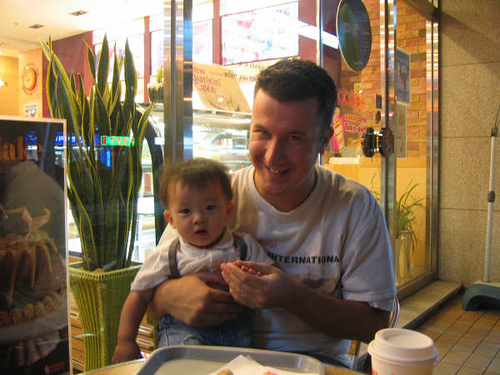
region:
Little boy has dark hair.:
[162, 163, 296, 255]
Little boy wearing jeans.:
[146, 305, 296, 368]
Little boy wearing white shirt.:
[143, 239, 252, 328]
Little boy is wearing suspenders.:
[158, 237, 218, 311]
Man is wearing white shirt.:
[274, 224, 461, 369]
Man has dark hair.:
[266, 90, 334, 118]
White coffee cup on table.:
[356, 327, 443, 371]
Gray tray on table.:
[156, 339, 228, 371]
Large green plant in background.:
[29, 89, 146, 368]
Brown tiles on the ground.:
[448, 327, 468, 365]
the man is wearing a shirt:
[148, 159, 408, 372]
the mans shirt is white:
[142, 154, 403, 368]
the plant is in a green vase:
[65, 256, 146, 373]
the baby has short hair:
[155, 152, 237, 217]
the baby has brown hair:
[153, 153, 238, 217]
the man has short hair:
[245, 56, 345, 151]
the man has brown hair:
[241, 46, 342, 159]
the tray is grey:
[130, 341, 328, 373]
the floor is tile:
[350, 274, 499, 374]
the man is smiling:
[261, 159, 291, 180]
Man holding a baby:
[111, 57, 391, 374]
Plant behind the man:
[31, 31, 150, 373]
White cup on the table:
[364, 325, 444, 373]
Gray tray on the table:
[136, 332, 331, 373]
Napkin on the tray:
[199, 347, 284, 373]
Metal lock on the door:
[357, 120, 401, 157]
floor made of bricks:
[416, 287, 498, 372]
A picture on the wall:
[0, 109, 77, 373]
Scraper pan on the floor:
[456, 119, 499, 315]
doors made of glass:
[323, 0, 443, 305]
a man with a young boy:
[108, 51, 423, 365]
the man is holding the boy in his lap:
[117, 35, 415, 360]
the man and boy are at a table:
[111, 57, 438, 373]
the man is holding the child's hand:
[110, 51, 430, 358]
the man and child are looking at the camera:
[114, 40, 417, 367]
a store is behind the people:
[68, 8, 478, 306]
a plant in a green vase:
[35, 36, 159, 356]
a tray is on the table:
[130, 317, 375, 373]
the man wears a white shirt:
[217, 63, 428, 344]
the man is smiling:
[201, 43, 433, 361]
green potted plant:
[61, 44, 136, 267]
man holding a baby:
[155, 69, 377, 339]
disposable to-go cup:
[369, 326, 438, 372]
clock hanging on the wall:
[23, 67, 35, 88]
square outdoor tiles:
[441, 312, 495, 369]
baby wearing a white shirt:
[160, 160, 250, 257]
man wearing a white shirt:
[249, 63, 342, 287]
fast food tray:
[151, 346, 209, 372]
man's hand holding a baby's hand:
[223, 255, 278, 307]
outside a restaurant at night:
[117, 5, 481, 364]